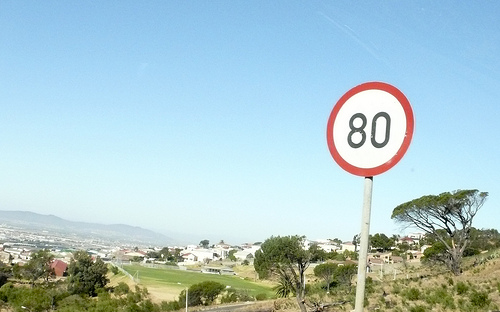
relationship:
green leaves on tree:
[255, 232, 314, 279] [253, 234, 312, 303]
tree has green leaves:
[253, 234, 312, 303] [255, 232, 314, 279]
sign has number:
[324, 81, 414, 177] [369, 111, 391, 148]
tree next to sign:
[250, 230, 325, 303] [324, 81, 414, 177]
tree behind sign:
[390, 185, 493, 273] [324, 81, 414, 177]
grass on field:
[116, 260, 273, 300] [101, 255, 284, 302]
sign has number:
[324, 81, 414, 177] [345, 109, 365, 149]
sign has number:
[324, 81, 414, 177] [369, 107, 391, 152]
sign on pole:
[324, 81, 414, 177] [347, 174, 378, 310]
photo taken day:
[4, 8, 480, 300] [4, 7, 484, 275]